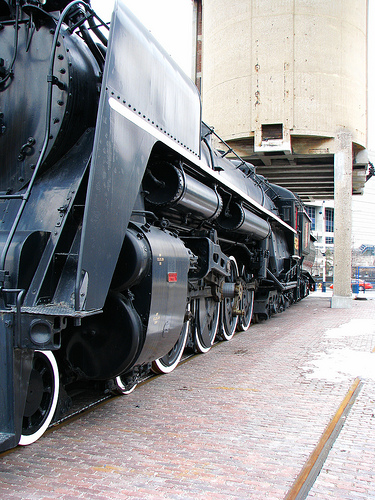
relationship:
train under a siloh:
[1, 1, 316, 446] [191, 1, 374, 309]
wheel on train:
[4, 340, 59, 456] [1, 1, 316, 446]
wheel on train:
[195, 254, 222, 355] [1, 1, 316, 446]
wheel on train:
[240, 257, 257, 332] [1, 1, 316, 446]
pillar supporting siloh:
[332, 141, 358, 307] [191, 1, 374, 309]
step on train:
[0, 421, 16, 456] [1, 1, 316, 446]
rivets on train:
[101, 85, 204, 158] [1, 1, 316, 446]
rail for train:
[52, 341, 222, 427] [1, 1, 316, 446]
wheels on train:
[11, 255, 255, 447] [1, 1, 316, 446]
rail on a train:
[200, 118, 279, 196] [1, 1, 316, 446]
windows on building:
[312, 208, 333, 231] [304, 200, 335, 296]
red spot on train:
[167, 274, 182, 284] [1, 1, 316, 446]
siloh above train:
[191, 1, 374, 309] [1, 1, 316, 446]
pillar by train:
[332, 141, 358, 307] [1, 1, 316, 446]